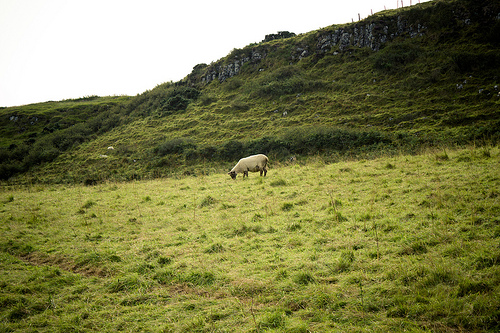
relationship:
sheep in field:
[224, 151, 272, 186] [79, 147, 378, 276]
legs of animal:
[260, 167, 262, 178] [230, 154, 271, 181]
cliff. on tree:
[324, 17, 440, 61] [263, 28, 297, 41]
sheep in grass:
[224, 151, 272, 186] [22, 172, 483, 330]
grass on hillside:
[35, 3, 499, 179] [1, 4, 498, 151]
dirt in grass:
[9, 250, 112, 282] [0, 0, 498, 331]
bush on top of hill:
[261, 27, 306, 42] [122, 11, 494, 125]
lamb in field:
[228, 151, 271, 181] [1, 159, 495, 331]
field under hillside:
[16, 188, 498, 299] [68, 27, 497, 148]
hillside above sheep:
[1, 4, 498, 151] [222, 149, 270, 180]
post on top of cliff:
[357, 11, 362, 21] [196, 2, 499, 92]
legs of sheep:
[231, 165, 304, 192] [215, 140, 291, 220]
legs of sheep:
[254, 168, 271, 178] [215, 125, 285, 189]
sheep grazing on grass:
[224, 151, 272, 186] [0, 139, 498, 329]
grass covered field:
[22, 172, 483, 330] [16, 188, 498, 299]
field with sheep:
[16, 188, 498, 299] [211, 146, 281, 187]